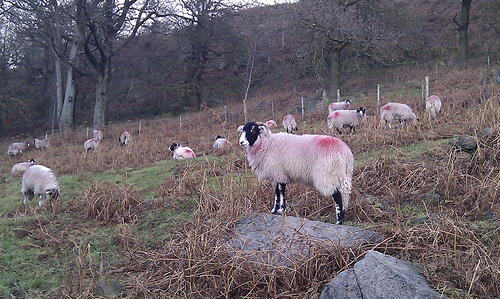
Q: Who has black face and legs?
A: Sheep.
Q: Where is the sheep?
A: Standing on a large rock.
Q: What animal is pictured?
A: Sheep.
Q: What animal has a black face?
A: Sheep.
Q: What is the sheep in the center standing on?
A: Large rock.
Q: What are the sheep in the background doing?
A: Eating grass.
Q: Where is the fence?
A: Behind the sheep in the distance.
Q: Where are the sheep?
A: Outside in a field.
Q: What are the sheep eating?
A: Brown and green grass.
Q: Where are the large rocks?
A: On the ground.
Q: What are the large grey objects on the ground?
A: Rocks.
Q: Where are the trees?
A: Behind the fence.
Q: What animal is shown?
A: Sheep.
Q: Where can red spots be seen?
A: Back ends of sheep.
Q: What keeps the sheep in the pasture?
A: Fence.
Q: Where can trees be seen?
A: Background.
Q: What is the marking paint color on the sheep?
A: Red.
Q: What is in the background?
A: The fence.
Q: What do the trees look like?
A: They are missing leaves.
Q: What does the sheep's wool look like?
A: Fluffy.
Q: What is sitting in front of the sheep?
A: Rocks.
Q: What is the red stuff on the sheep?
A: Paint.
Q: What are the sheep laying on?
A: Grass.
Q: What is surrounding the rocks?
A: Dead grass.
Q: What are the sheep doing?
A: Grazing.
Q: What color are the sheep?
A: White.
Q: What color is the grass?
A: Green.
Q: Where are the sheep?
A: On the grass.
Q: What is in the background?
A: Trees.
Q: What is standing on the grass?
A: Sheep.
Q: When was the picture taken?
A: Daytime.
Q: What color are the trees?
A: Brown.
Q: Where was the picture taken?
A: On a hill.